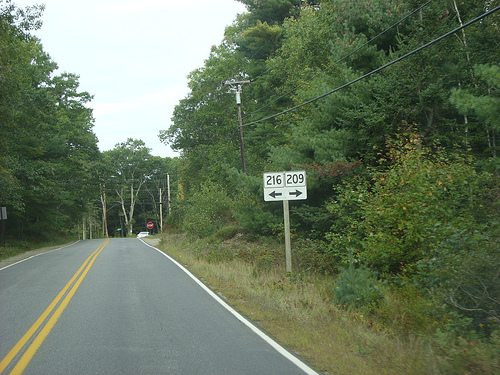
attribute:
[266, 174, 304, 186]
numbers — black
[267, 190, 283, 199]
arrow — black, pointing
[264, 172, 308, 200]
sign — black, white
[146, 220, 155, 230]
sign — red, white, far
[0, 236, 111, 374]
lines — yellow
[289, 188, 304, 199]
arrow — black, pointing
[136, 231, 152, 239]
car — white, far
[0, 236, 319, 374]
lines — white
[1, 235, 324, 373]
road — gray, grey